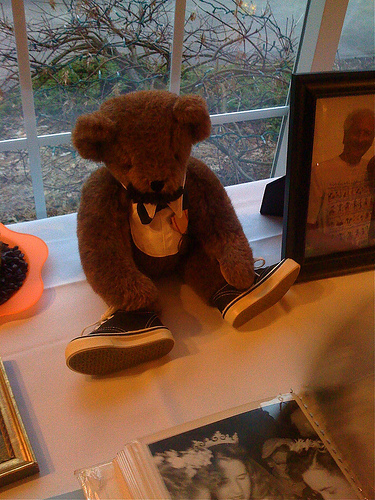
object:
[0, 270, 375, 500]
tabletop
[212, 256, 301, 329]
shoes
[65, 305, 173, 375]
shoes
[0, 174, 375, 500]
table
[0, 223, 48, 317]
bowl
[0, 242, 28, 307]
stones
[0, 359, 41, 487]
picture frame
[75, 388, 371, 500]
album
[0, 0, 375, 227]
window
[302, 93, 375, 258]
photo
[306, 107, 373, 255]
man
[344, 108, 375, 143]
hair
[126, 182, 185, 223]
bowtie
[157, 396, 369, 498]
photo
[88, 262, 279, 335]
black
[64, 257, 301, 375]
white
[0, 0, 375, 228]
framing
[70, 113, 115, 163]
ear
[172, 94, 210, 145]
ear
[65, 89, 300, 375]
bear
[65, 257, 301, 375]
shoes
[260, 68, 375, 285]
frame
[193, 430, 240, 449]
tiara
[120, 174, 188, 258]
bib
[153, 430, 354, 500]
women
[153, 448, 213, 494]
flowers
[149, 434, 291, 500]
lady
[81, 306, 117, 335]
laces